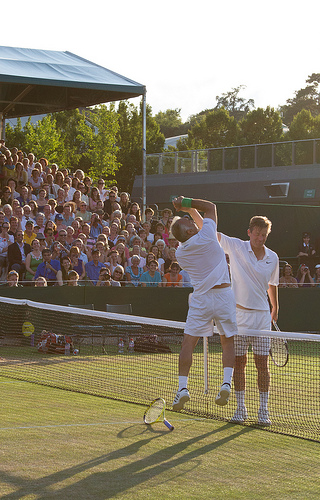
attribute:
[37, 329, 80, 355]
bag — red, gray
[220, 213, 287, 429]
player — tennis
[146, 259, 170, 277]
shirt — teal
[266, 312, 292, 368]
racket — tennis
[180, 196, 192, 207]
wristband — green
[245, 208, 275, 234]
hair — brown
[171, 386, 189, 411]
shoe — tennis, white, black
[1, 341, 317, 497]
grass — green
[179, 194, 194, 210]
sweatband — green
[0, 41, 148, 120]
canopy — green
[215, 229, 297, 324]
shirt — white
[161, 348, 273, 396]
socks — white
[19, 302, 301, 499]
tennis court — green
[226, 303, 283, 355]
shorts — white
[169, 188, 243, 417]
tennis player — male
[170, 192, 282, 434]
tennis player — male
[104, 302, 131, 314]
green chair — empty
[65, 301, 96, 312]
green chair — empty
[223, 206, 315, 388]
player — tennis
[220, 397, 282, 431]
sneakers — white 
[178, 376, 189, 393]
sock — white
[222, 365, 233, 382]
sock — white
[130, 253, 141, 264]
hair — white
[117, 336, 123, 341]
cap — red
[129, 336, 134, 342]
cap — red